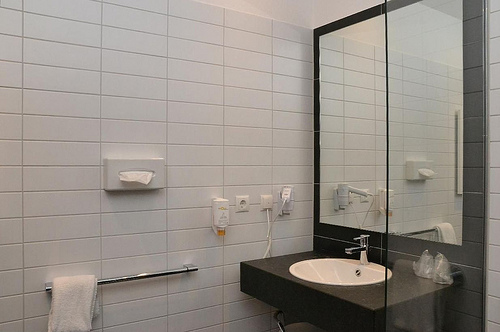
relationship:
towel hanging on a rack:
[48, 274, 98, 330] [45, 264, 199, 291]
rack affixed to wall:
[45, 264, 199, 291] [3, 4, 317, 330]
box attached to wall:
[102, 155, 169, 191] [3, 4, 317, 330]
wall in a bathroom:
[385, 0, 499, 328] [1, 0, 498, 328]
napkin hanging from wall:
[117, 170, 156, 185] [3, 4, 317, 330]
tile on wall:
[23, 10, 102, 46] [3, 4, 317, 330]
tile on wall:
[21, 61, 103, 93] [3, 4, 317, 330]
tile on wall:
[21, 34, 102, 70] [3, 4, 317, 330]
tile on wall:
[99, 48, 169, 77] [3, 4, 317, 330]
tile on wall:
[21, 113, 102, 144] [3, 4, 317, 330]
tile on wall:
[21, 103, 79, 212] [27, 26, 301, 286]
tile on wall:
[21, 116, 91, 226] [30, 27, 284, 269]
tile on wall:
[25, 125, 93, 224] [21, 50, 327, 277]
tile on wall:
[28, 108, 104, 211] [16, 59, 316, 319]